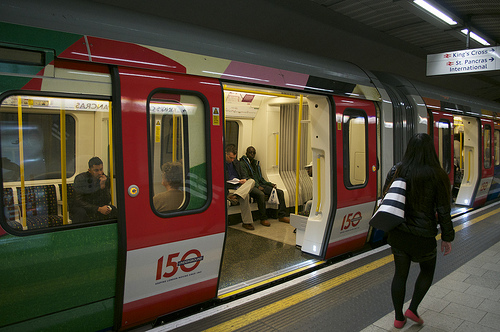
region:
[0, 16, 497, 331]
a subway train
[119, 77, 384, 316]
open red and white doors of train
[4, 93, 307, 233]
yellow bars running down center of interior of train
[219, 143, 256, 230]
man sitting with one leg crossed over the other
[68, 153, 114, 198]
man's hand beneath his chin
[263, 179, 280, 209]
man holding a bag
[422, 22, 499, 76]
direction sign with arrows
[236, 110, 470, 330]
woman walking next to train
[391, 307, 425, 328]
woman wearing pink flats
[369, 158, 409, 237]
woman carrying an over-sized striped black and white bag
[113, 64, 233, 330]
Metro door on the london undergound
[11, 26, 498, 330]
subway train in the London Underground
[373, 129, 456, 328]
Female walking away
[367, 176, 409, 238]
black and white striped bag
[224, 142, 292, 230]
two men sitting on a subway train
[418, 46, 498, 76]
directional sign in a subway station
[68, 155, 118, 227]
man sitting in a subway car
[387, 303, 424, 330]
women's red flats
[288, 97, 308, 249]
yellow hand rail in a subway car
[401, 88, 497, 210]
subway train car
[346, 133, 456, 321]
Person walking on walkway.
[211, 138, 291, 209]
People sitting in the subway.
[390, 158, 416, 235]
lady carrying black and white purse.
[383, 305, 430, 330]
Shoes are pink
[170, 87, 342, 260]
The subway door is open.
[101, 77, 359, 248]
The train is red green and white.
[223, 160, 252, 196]
Man reading newspaper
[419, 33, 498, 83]
A white sign hanging from ceiling.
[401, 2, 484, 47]
Lights on the ceiling.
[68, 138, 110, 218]
Man sitting on the train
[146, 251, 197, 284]
red numbers on white background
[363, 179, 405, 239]
white and black bag of woman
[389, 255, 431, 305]
black tights of woman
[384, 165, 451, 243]
black coat of woman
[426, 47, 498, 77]
white sign hanging over platform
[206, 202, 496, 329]
yellow line painted on platform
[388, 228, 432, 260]
black skirt of woman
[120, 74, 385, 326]
open doors of train car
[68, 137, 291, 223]
people sitting in train car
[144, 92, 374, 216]
windows of train doors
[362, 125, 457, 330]
woman walking in subway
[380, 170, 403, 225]
black and white purse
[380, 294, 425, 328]
red shoes on feet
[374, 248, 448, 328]
black leggings on woman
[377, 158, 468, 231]
black jacket on woman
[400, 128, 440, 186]
long brown hair on woman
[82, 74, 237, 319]
red and white door of subway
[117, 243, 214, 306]
red numbers on side of subway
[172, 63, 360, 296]
open door of subway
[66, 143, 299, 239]
people sitting on the subway